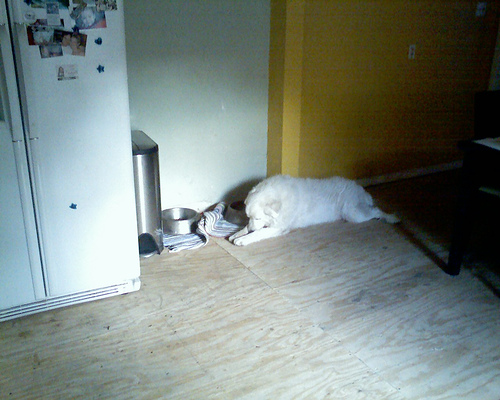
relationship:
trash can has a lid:
[130, 128, 166, 258] [130, 129, 156, 155]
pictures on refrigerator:
[17, 3, 115, 80] [1, 0, 144, 320]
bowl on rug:
[160, 206, 198, 237] [148, 208, 240, 253]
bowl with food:
[160, 208, 197, 236] [171, 216, 192, 224]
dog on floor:
[221, 171, 399, 251] [4, 158, 483, 396]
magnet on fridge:
[96, 65, 108, 74] [3, 2, 145, 328]